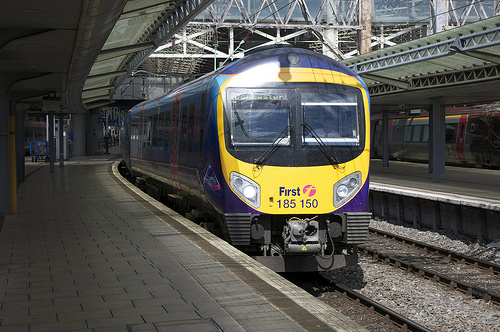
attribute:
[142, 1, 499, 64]
beams — metal beams 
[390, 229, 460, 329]
tracks — steel, railroad tracks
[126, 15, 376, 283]
train — blue , yellow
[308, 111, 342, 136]
conductor — train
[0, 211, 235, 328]
bricks — concrete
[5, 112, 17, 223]
pole — yellow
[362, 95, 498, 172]
train — track, grey, red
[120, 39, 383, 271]
train — purple, yellow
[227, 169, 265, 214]
light — front lights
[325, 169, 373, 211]
light — front lights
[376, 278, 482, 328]
track — railroad track 